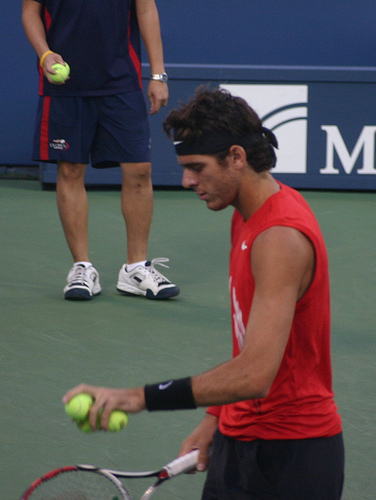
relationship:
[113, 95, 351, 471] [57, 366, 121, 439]
man has balls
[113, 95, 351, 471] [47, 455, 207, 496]
man has racket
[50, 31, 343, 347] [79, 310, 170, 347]
men on court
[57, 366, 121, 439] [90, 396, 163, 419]
balls in hand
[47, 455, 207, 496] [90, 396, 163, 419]
racket in hand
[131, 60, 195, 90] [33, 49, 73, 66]
watch on wrist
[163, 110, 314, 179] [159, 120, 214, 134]
headband on forehead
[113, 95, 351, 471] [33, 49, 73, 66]
man has wrist